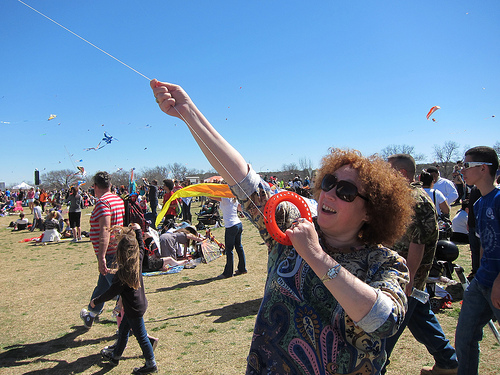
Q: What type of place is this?
A: It is a field.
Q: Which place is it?
A: It is a field.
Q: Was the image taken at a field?
A: Yes, it was taken in a field.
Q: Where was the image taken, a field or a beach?
A: It was taken at a field.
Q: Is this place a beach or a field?
A: It is a field.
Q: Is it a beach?
A: No, it is a field.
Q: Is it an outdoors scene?
A: Yes, it is outdoors.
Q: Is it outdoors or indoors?
A: It is outdoors.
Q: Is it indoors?
A: No, it is outdoors.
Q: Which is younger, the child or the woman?
A: The child is younger than the woman.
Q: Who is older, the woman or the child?
A: The woman is older than the child.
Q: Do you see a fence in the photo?
A: No, there are no fences.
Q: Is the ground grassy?
A: Yes, the ground is grassy.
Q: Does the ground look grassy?
A: Yes, the ground is grassy.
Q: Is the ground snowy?
A: No, the ground is grassy.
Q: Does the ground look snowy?
A: No, the ground is grassy.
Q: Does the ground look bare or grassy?
A: The ground is grassy.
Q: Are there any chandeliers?
A: No, there are no chandeliers.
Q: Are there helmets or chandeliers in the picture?
A: No, there are no chandeliers or helmets.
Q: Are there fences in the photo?
A: No, there are no fences.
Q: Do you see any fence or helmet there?
A: No, there are no fences or helmets.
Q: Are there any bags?
A: No, there are no bags.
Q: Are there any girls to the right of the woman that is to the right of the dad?
A: Yes, there is a girl to the right of the woman.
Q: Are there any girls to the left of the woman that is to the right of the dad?
A: No, the girl is to the right of the woman.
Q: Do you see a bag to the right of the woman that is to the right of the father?
A: No, there is a girl to the right of the woman.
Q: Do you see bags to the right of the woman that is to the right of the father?
A: No, there is a girl to the right of the woman.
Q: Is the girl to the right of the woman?
A: Yes, the girl is to the right of the woman.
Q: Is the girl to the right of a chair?
A: No, the girl is to the right of the woman.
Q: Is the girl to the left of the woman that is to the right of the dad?
A: No, the girl is to the right of the woman.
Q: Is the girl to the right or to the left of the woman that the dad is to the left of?
A: The girl is to the right of the woman.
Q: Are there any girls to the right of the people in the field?
A: Yes, there is a girl to the right of the people.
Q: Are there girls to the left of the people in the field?
A: No, the girl is to the right of the people.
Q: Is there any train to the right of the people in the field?
A: No, there is a girl to the right of the people.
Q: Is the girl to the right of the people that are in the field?
A: Yes, the girl is to the right of the people.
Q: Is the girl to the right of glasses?
A: No, the girl is to the right of the people.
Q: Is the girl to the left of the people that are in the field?
A: No, the girl is to the right of the people.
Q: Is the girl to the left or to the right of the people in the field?
A: The girl is to the right of the people.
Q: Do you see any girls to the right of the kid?
A: Yes, there is a girl to the right of the kid.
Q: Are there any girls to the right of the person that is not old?
A: Yes, there is a girl to the right of the kid.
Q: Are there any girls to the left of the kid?
A: No, the girl is to the right of the kid.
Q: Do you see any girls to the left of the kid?
A: No, the girl is to the right of the kid.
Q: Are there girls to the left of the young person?
A: No, the girl is to the right of the kid.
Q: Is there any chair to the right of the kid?
A: No, there is a girl to the right of the kid.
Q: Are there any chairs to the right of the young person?
A: No, there is a girl to the right of the kid.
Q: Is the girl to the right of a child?
A: Yes, the girl is to the right of a child.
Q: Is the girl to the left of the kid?
A: No, the girl is to the right of the kid.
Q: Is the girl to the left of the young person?
A: No, the girl is to the right of the kid.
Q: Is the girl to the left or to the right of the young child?
A: The girl is to the right of the kid.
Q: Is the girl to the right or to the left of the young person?
A: The girl is to the right of the kid.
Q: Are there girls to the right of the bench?
A: Yes, there is a girl to the right of the bench.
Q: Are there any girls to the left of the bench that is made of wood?
A: No, the girl is to the right of the bench.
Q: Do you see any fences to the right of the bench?
A: No, there is a girl to the right of the bench.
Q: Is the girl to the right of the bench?
A: Yes, the girl is to the right of the bench.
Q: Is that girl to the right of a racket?
A: No, the girl is to the right of the bench.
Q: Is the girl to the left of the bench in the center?
A: No, the girl is to the right of the bench.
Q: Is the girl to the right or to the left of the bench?
A: The girl is to the right of the bench.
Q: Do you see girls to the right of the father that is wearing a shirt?
A: Yes, there is a girl to the right of the father.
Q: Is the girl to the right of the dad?
A: Yes, the girl is to the right of the dad.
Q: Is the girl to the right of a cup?
A: No, the girl is to the right of the dad.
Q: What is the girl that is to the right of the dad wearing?
A: The girl is wearing a shirt.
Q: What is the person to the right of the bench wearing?
A: The girl is wearing a shirt.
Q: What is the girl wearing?
A: The girl is wearing a shirt.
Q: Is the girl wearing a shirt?
A: Yes, the girl is wearing a shirt.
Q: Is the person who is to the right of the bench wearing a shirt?
A: Yes, the girl is wearing a shirt.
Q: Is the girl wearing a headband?
A: No, the girl is wearing a shirt.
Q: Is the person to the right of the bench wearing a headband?
A: No, the girl is wearing a shirt.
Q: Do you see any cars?
A: No, there are no cars.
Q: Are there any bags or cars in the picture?
A: No, there are no cars or bags.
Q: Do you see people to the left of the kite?
A: Yes, there are people to the left of the kite.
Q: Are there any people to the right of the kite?
A: No, the people are to the left of the kite.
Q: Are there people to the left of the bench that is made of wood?
A: Yes, there are people to the left of the bench.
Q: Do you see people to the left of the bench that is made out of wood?
A: Yes, there are people to the left of the bench.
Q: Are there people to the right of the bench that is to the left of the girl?
A: No, the people are to the left of the bench.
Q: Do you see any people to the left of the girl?
A: Yes, there are people to the left of the girl.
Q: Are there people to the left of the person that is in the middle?
A: Yes, there are people to the left of the girl.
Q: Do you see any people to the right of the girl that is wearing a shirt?
A: No, the people are to the left of the girl.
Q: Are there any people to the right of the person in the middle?
A: No, the people are to the left of the girl.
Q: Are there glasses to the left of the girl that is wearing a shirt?
A: No, there are people to the left of the girl.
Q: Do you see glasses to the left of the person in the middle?
A: No, there are people to the left of the girl.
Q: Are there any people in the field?
A: Yes, there are people in the field.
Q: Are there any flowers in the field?
A: No, there are people in the field.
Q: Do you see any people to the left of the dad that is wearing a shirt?
A: Yes, there are people to the left of the dad.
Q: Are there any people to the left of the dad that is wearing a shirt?
A: Yes, there are people to the left of the dad.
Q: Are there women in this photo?
A: Yes, there is a woman.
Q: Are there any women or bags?
A: Yes, there is a woman.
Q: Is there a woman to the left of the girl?
A: Yes, there is a woman to the left of the girl.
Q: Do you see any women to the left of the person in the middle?
A: Yes, there is a woman to the left of the girl.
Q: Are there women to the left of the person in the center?
A: Yes, there is a woman to the left of the girl.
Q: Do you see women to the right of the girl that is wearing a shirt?
A: No, the woman is to the left of the girl.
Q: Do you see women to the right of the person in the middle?
A: No, the woman is to the left of the girl.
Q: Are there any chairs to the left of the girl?
A: No, there is a woman to the left of the girl.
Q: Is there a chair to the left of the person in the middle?
A: No, there is a woman to the left of the girl.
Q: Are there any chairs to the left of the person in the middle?
A: No, there is a woman to the left of the girl.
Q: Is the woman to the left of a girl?
A: Yes, the woman is to the left of a girl.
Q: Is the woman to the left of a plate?
A: No, the woman is to the left of a girl.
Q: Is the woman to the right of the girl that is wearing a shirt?
A: No, the woman is to the left of the girl.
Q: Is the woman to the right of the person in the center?
A: No, the woman is to the left of the girl.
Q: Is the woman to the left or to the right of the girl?
A: The woman is to the left of the girl.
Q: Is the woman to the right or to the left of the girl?
A: The woman is to the left of the girl.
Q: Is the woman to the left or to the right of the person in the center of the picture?
A: The woman is to the left of the girl.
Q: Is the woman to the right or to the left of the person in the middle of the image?
A: The woman is to the left of the girl.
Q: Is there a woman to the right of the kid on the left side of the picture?
A: Yes, there is a woman to the right of the child.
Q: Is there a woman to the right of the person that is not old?
A: Yes, there is a woman to the right of the child.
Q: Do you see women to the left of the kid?
A: No, the woman is to the right of the kid.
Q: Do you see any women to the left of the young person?
A: No, the woman is to the right of the kid.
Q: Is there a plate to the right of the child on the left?
A: No, there is a woman to the right of the kid.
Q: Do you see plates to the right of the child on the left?
A: No, there is a woman to the right of the kid.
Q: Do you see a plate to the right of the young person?
A: No, there is a woman to the right of the kid.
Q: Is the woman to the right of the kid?
A: Yes, the woman is to the right of the kid.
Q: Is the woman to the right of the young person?
A: Yes, the woman is to the right of the kid.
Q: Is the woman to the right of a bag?
A: No, the woman is to the right of the kid.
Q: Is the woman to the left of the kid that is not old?
A: No, the woman is to the right of the child.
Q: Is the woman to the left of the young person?
A: No, the woman is to the right of the child.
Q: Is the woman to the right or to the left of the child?
A: The woman is to the right of the child.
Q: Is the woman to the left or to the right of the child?
A: The woman is to the right of the child.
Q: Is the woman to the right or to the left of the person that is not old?
A: The woman is to the right of the child.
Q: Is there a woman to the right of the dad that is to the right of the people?
A: Yes, there is a woman to the right of the father.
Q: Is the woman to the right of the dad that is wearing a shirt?
A: Yes, the woman is to the right of the dad.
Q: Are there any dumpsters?
A: No, there are no dumpsters.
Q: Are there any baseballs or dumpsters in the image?
A: No, there are no dumpsters or baseballs.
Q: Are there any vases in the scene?
A: No, there are no vases.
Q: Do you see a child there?
A: Yes, there is a child.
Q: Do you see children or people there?
A: Yes, there is a child.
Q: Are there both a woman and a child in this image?
A: Yes, there are both a child and a woman.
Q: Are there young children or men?
A: Yes, there is a young child.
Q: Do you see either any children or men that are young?
A: Yes, the child is young.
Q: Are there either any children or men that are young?
A: Yes, the child is young.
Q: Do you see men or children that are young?
A: Yes, the child is young.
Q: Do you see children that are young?
A: Yes, there is a young child.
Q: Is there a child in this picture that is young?
A: Yes, there is a child that is young.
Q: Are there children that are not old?
A: Yes, there is an young child.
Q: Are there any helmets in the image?
A: No, there are no helmets.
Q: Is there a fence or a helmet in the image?
A: No, there are no helmets or fences.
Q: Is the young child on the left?
A: Yes, the kid is on the left of the image.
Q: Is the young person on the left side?
A: Yes, the kid is on the left of the image.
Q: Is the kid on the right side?
A: No, the kid is on the left of the image.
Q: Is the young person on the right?
A: No, the kid is on the left of the image.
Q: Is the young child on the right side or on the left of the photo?
A: The child is on the left of the image.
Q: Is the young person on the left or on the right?
A: The child is on the left of the image.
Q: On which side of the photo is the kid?
A: The kid is on the left of the image.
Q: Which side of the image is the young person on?
A: The kid is on the left of the image.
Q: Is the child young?
A: Yes, the child is young.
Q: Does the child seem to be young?
A: Yes, the child is young.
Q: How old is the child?
A: The child is young.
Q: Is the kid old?
A: No, the kid is young.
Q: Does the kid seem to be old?
A: No, the kid is young.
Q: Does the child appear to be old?
A: No, the child is young.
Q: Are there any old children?
A: No, there is a child but he is young.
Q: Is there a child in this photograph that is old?
A: No, there is a child but he is young.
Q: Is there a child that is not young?
A: No, there is a child but he is young.